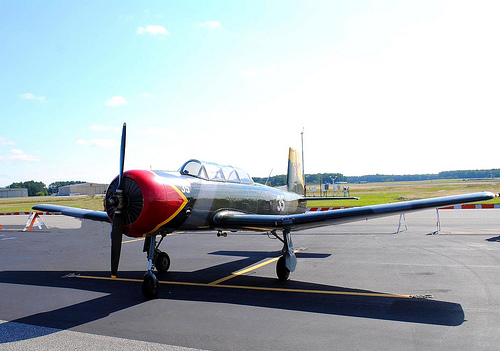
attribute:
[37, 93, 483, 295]
airplane — vintage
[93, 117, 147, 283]
propeller — small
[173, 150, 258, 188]
hatch — glass, clear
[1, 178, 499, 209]
grass — green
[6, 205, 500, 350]
asphalt — gray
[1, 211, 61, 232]
barrier — red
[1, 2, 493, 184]
sky — blue, hazy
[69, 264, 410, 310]
line — yellow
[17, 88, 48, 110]
cloud — small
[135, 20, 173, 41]
cloud — small, yes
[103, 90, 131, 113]
cloud — small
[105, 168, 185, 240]
nose — red